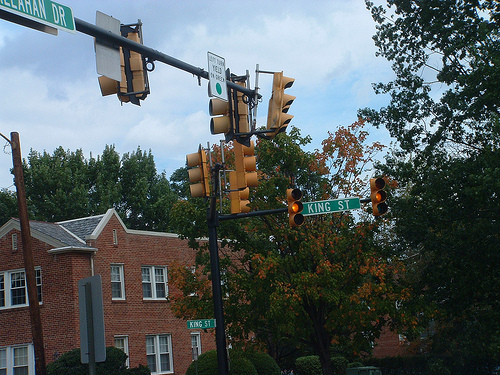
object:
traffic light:
[269, 69, 300, 93]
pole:
[74, 17, 263, 101]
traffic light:
[202, 95, 238, 116]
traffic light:
[93, 72, 131, 102]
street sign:
[0, 1, 76, 29]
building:
[0, 207, 424, 375]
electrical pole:
[8, 130, 47, 373]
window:
[109, 263, 125, 300]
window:
[152, 265, 167, 300]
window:
[146, 335, 157, 374]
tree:
[164, 117, 407, 375]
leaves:
[28, 127, 171, 205]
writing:
[208, 53, 226, 83]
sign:
[206, 52, 230, 103]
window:
[111, 228, 120, 247]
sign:
[299, 195, 362, 219]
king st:
[306, 199, 354, 213]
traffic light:
[285, 186, 306, 199]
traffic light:
[369, 201, 392, 218]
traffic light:
[228, 196, 257, 214]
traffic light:
[287, 198, 305, 213]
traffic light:
[183, 150, 204, 165]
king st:
[186, 319, 216, 328]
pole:
[215, 205, 289, 223]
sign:
[75, 273, 107, 374]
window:
[6, 270, 27, 306]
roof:
[1, 214, 104, 246]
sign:
[95, 12, 124, 84]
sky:
[157, 1, 356, 48]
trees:
[0, 139, 181, 230]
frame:
[5, 344, 34, 373]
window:
[9, 345, 29, 375]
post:
[206, 189, 231, 373]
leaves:
[302, 117, 380, 169]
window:
[0, 347, 7, 373]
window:
[191, 332, 201, 362]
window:
[114, 337, 124, 352]